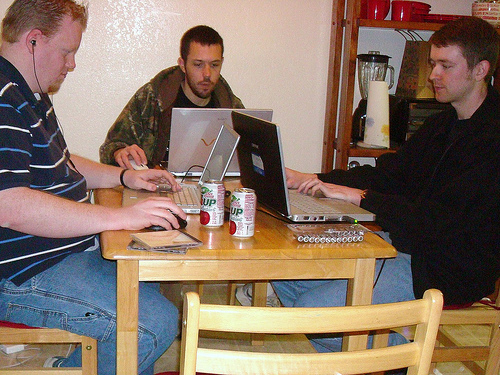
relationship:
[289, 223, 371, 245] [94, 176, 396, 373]
package on table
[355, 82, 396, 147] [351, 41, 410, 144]
paper towels in front of blender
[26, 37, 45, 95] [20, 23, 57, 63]
ear bud in ear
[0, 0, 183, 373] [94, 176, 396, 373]
man sitting at table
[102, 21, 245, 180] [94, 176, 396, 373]
man sitting at table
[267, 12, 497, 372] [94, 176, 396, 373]
man sitting at table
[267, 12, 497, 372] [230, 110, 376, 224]
man using computer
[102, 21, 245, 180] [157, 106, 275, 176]
man using computer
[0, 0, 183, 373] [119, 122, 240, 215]
man using computer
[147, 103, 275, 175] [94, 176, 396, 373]
computer on table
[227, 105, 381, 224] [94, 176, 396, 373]
computer on table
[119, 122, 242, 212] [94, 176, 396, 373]
computer on table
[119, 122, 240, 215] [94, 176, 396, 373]
computer kept in table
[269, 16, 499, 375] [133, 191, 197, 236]
man holding mouse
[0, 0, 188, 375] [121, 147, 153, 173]
man holding mouse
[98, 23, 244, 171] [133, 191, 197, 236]
man holding mouse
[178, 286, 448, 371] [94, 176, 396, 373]
chair near table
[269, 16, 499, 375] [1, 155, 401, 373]
man sitting at table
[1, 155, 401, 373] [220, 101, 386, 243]
table on laptop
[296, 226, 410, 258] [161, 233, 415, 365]
batteries sitting on table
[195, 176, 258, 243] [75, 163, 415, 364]
sodas on table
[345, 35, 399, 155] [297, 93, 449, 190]
blender on shelf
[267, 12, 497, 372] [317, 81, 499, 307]
man wearing coat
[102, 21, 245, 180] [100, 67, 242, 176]
man wearing coat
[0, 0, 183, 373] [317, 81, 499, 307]
man wearing coat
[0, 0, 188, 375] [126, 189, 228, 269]
man touching mouse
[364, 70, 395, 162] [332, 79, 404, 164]
cup upside down on shelf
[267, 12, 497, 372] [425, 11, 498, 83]
man has short hair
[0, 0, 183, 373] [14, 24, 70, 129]
man wearing ear buds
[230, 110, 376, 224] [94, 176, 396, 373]
computer on table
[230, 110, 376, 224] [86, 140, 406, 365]
computer on table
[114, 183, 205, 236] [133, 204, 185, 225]
hand on mouse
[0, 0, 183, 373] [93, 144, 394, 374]
man sitting at table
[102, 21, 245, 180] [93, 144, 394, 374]
man sitting at table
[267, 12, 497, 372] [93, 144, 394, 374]
man sitting at table